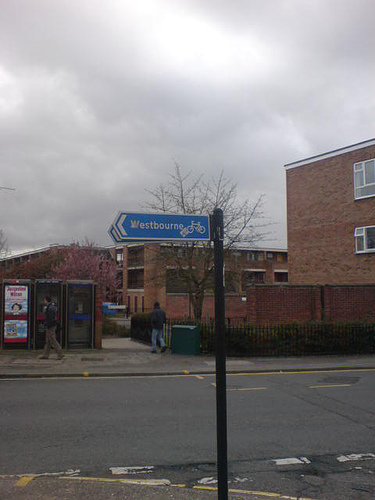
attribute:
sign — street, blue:
[110, 207, 210, 240]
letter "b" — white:
[151, 218, 160, 233]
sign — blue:
[106, 208, 213, 247]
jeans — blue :
[152, 327, 163, 352]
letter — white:
[144, 220, 150, 229]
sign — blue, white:
[111, 210, 211, 241]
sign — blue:
[97, 210, 189, 247]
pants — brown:
[42, 321, 63, 354]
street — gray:
[0, 365, 373, 474]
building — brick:
[284, 133, 374, 286]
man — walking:
[142, 280, 172, 343]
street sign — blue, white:
[117, 208, 207, 238]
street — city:
[40, 187, 373, 402]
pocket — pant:
[45, 305, 60, 321]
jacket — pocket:
[147, 307, 168, 330]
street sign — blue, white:
[108, 210, 210, 248]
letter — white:
[156, 221, 167, 232]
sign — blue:
[108, 204, 216, 245]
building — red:
[259, 140, 345, 277]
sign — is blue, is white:
[101, 166, 317, 294]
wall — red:
[245, 280, 374, 327]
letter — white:
[130, 217, 200, 233]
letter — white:
[150, 215, 161, 232]